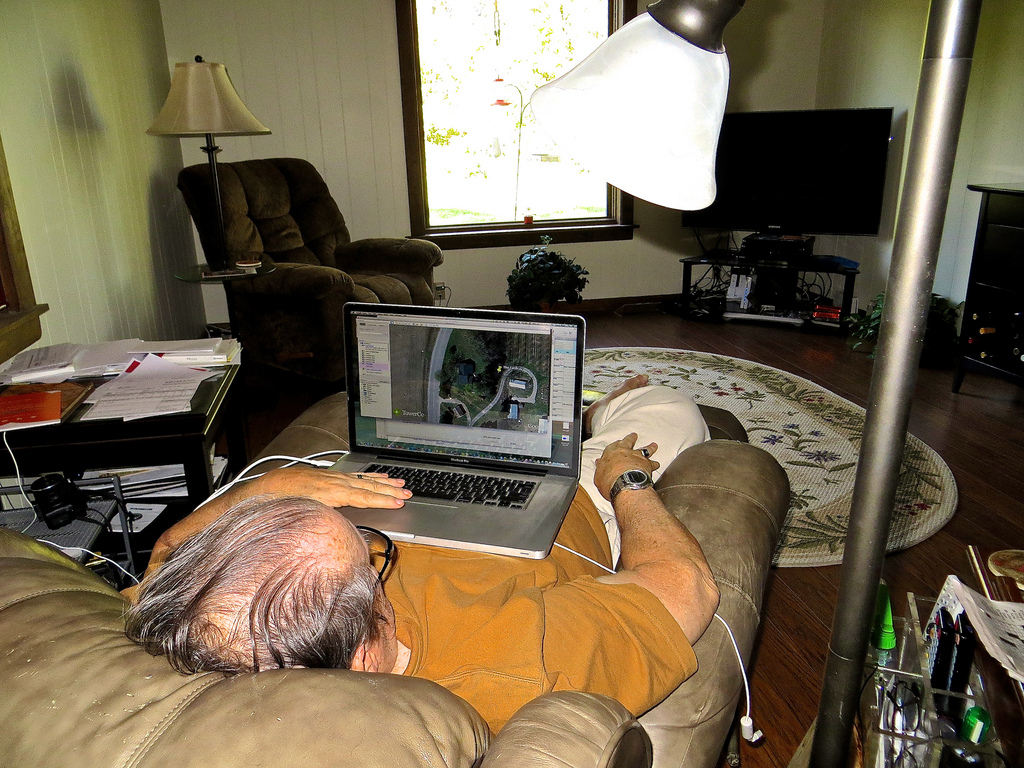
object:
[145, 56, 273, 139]
lampshade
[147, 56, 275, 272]
lamp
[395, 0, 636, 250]
window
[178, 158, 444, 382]
recliner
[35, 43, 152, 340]
shadow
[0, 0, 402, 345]
wall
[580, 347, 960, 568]
area rug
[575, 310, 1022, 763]
floor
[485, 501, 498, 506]
key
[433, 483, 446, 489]
key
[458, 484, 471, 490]
key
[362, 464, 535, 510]
keyboard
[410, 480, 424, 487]
key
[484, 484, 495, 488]
key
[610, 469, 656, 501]
watch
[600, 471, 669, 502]
wrist